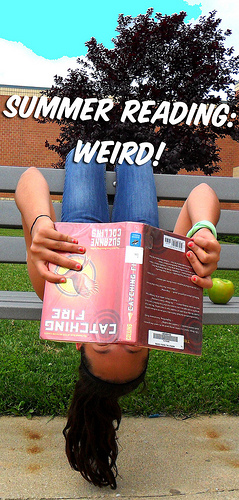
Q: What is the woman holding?
A: A book.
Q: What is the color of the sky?
A: Blue and white.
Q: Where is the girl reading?
A: On a bench.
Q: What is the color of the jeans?
A: Blue.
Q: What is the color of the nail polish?
A: Red.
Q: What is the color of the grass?
A: Green.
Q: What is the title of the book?
A: Catching fire.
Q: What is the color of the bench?
A: Gray.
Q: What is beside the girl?
A: An apple.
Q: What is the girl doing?
A: She's upside down.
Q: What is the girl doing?
A: Reading.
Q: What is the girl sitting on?
A: A bench.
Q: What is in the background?
A: A building.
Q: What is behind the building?
A: A tree.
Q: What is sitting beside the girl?
A: An apple.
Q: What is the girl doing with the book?
A: Reading.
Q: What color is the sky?
A: Blue.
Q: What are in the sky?
A: Clouds.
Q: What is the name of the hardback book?
A: Catching Fire.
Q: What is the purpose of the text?
A: A label for photo.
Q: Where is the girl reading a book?
A: Upside down on a bench.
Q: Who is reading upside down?
A: A girl.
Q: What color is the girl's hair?
A: Black.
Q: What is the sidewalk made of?
A: Gray cement.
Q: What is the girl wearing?
A: Blue jeans.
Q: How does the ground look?
A: Green and grassy.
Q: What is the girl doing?
A: Hanging upside down.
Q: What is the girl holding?
A: A book.